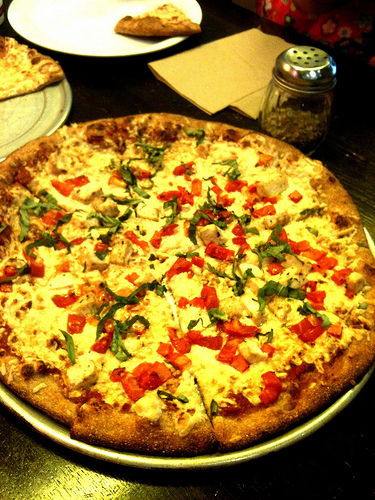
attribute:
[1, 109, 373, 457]
pizza — whole, large, cut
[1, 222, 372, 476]
tray — silver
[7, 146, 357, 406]
toppings — green, red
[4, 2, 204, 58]
plate — white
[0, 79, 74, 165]
pan — silver, gray, metal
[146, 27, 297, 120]
napkin — brown, paper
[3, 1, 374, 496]
table — wood, brown, black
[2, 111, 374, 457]
crust — brown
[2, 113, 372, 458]
slices — triangular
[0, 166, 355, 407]
tomatoes — red